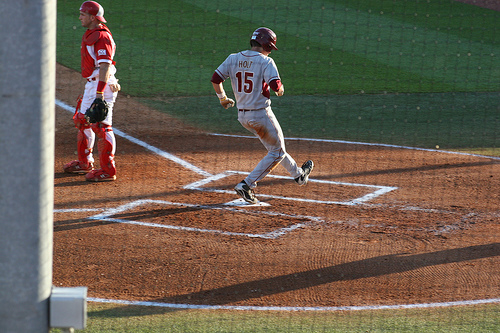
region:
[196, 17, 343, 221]
player 15 touching home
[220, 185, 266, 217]
home bases with a foot on it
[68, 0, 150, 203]
catcher not paying attention at all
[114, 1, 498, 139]
baseball field with green grass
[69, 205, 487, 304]
freshly raked dirt on the diamond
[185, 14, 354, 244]
baseball player in action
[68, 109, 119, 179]
red shin pads on a player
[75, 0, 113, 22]
red and white baseball cap worn backwards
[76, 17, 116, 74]
red shirt with white details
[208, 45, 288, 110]
grey shirt with marroon details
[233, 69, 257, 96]
number 15 on the jersey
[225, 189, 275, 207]
home plate in the red soil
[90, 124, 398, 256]
white chalk marks on the soil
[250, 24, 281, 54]
a marroon helmet on a player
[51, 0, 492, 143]
dark green grass of the infield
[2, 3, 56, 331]
a silver pole behind the backstop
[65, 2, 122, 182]
basball catcher standing on the sideline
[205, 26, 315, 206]
baseball player running in to home plate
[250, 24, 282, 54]
baseball player's red helmet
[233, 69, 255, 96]
red number on the back of the player's shirt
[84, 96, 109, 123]
black baseball mitt the catcher is holding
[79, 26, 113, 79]
orange chest guard the catcher is wearing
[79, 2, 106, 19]
red and white hat the catcher is wearing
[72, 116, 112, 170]
orange shin guards the catcher is wearing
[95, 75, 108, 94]
orange sweatband on the catcher's arm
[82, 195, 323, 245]
white lines marking the batter's box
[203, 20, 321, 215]
player with foot on home plate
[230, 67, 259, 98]
number 15 on player's jersey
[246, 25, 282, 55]
sport safety baseball helmet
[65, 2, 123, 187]
baseball catcher facing left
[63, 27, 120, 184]
red and white sports uniform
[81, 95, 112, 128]
black catcher's mitt on left hand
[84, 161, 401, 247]
boundary lines of batter's boxes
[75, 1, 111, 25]
red and white ball cap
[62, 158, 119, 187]
red and white athletic shoes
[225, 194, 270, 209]
a white home base plate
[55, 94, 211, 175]
a white marked foul line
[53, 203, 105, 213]
a white marked foul line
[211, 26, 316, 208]
a baseball player running to home base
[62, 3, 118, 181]
a baseball catcher standing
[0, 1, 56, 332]
a grey metal pole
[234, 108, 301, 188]
a pair of grey pants covered with dirt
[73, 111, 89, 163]
a red shin and knee pad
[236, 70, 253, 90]
the number 15 on the back of a jersey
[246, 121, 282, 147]
dirt on the back of pants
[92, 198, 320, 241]
a white painted square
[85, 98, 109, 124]
a black glove on the catcher's hand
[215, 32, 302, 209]
A baseball player With a white and red uniform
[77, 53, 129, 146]
Baseball player with a glove